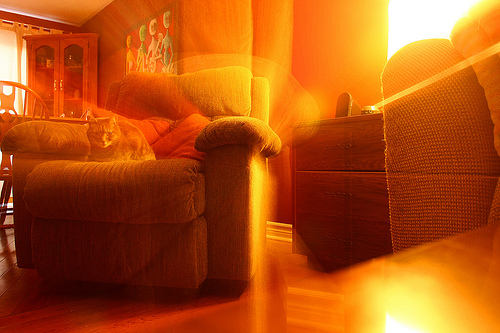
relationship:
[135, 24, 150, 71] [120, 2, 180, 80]
alien in picture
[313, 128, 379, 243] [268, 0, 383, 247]
wooden beside wall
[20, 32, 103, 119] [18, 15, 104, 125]
cabinet in corner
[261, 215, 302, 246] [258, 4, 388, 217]
baseboard on wall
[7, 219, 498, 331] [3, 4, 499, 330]
floor in room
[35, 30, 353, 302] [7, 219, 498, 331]
chair on floor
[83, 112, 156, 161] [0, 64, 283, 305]
cat in chair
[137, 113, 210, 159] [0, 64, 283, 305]
pillow on chair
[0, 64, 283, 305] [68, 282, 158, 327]
chair on floor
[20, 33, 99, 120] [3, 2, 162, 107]
cabinet against wall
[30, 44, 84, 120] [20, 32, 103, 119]
glass panes on cabinet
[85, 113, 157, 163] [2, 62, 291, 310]
cat laying in chair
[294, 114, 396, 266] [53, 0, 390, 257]
cabinet on wall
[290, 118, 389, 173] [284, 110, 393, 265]
drawer on cabinet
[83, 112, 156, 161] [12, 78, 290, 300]
cat on chair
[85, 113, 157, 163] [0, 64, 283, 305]
cat on chair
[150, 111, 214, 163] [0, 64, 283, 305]
pillow on chair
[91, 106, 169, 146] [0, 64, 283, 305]
pillow on chair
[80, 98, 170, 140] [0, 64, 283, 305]
pillow on chair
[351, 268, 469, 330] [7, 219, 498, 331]
light reflection on floor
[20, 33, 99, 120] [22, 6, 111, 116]
cabinet in corner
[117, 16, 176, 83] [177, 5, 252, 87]
art on wall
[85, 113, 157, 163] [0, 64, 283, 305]
cat sitting in chair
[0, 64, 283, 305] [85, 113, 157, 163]
chair with cat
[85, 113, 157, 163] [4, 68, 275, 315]
cat in chair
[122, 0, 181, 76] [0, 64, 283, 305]
art behind chair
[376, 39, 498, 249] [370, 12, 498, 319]
arm of chair